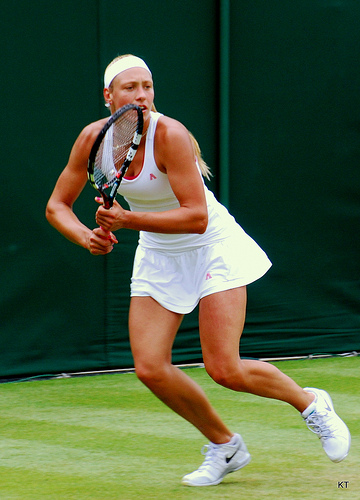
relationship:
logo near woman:
[335, 480, 351, 490] [41, 50, 355, 488]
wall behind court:
[1, 1, 359, 367] [2, 354, 359, 499]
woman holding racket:
[41, 50, 355, 488] [77, 101, 145, 254]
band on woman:
[101, 53, 159, 87] [41, 50, 355, 488]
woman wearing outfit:
[41, 50, 355, 488] [89, 112, 279, 318]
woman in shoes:
[41, 50, 355, 488] [169, 387, 357, 493]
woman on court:
[41, 50, 355, 488] [2, 354, 359, 499]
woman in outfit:
[41, 50, 355, 488] [89, 112, 279, 318]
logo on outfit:
[146, 173, 158, 187] [89, 112, 279, 318]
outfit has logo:
[89, 112, 279, 318] [146, 173, 158, 187]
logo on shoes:
[222, 447, 245, 463] [169, 387, 357, 493]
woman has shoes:
[41, 50, 355, 488] [169, 387, 357, 493]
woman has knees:
[41, 50, 355, 488] [121, 357, 246, 388]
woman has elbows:
[41, 50, 355, 488] [28, 195, 213, 234]